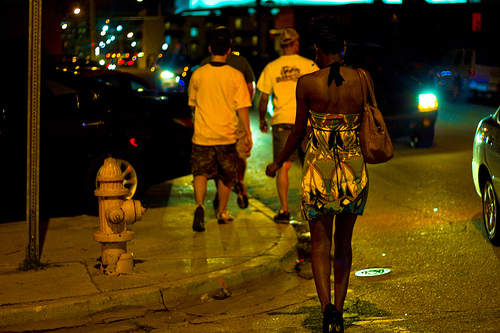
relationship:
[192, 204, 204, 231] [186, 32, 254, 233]
sandal on a man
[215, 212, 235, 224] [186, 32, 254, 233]
sandal on a man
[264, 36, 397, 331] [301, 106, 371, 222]
person wearing dress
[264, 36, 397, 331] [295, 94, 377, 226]
person wearing dress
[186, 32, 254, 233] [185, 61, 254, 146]
man wearing shirt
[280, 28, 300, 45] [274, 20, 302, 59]
cap on head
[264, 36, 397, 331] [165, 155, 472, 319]
person on street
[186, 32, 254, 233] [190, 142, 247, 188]
man wears shorts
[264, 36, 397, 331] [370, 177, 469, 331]
person walks on street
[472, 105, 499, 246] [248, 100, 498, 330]
car on street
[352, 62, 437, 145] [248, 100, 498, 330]
car on street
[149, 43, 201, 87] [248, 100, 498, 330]
car on street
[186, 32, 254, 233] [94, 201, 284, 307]
man on sidewalk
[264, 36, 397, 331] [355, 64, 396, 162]
person carries purse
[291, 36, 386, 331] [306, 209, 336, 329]
person has leg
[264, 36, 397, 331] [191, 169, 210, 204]
person has leg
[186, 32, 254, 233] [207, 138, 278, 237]
man has leg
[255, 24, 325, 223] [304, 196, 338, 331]
man has leg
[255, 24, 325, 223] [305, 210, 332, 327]
man has leg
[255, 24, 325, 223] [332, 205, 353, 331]
man has leg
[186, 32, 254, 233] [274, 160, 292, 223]
man has leg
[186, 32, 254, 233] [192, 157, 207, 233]
man has leg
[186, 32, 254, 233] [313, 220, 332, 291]
man has leg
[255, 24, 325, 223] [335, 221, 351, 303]
man has leg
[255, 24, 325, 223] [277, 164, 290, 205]
man has leg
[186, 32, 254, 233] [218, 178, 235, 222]
man has leg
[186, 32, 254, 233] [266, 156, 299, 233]
man has leg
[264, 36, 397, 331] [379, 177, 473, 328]
person walks in street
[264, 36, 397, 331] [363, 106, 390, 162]
person has purse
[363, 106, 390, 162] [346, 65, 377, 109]
purse on shoulder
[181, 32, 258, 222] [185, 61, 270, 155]
man wears shirt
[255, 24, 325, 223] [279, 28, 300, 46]
man wears cap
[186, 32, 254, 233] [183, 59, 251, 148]
man wears shirt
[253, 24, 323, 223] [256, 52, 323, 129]
man wears shirt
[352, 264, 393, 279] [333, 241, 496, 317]
drain on ground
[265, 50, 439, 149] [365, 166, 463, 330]
car on street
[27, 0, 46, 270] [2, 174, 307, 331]
pole on sidewalk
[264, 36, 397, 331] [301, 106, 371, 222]
person wears dress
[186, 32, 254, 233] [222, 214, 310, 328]
man walk down street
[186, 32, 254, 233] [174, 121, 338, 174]
man wear shorts